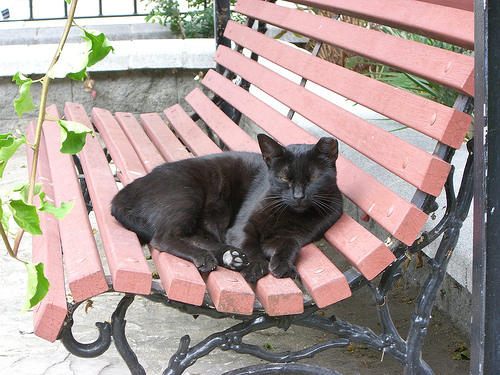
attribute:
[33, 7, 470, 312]
wooden beams — pastel , red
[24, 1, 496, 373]
bench — red, wooden, curved, wood, iron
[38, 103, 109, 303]
wood slat — red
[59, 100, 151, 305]
wood slat — red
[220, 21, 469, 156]
wood slat — red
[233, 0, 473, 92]
wood slat — red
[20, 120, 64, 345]
slat — wood , red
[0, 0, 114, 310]
branch — tree, hanging, leafy, green, low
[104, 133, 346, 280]
cat — black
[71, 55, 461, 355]
bench — iron, wood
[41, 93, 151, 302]
slat — red, wood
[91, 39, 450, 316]
seat — curved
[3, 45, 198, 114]
blocks — grey, granite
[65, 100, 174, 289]
slat — wood, red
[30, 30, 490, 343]
seat — red